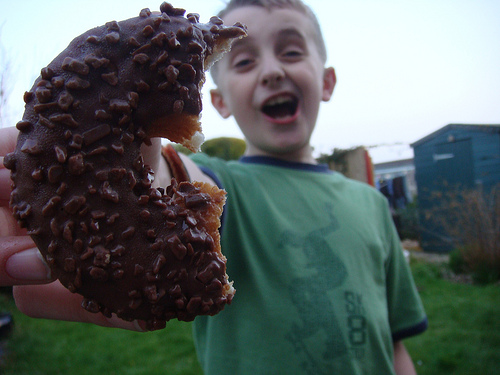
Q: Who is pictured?
A: Boy.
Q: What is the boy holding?
A: A donut.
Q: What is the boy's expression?
A: Happy.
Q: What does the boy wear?
A: A green shirt.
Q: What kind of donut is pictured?
A: Chocolate sprinkles and half eaten.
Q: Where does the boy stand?
A: On grass.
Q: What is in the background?
A: Buildings.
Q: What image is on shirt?
A: Silhouette of a skateboarder.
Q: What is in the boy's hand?
A: Chocolate doughnut.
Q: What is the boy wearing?
A: Green t-shirt.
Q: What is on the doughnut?
A: Chocolate sprinkles.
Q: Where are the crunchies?
A: On doughnut.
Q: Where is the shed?
A: Behind the boy.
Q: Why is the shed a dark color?
A: Owner painted green.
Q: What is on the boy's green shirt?
A: Black design.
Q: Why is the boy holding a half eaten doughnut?
A: Showing it to friends.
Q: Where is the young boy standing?
A: Center forefront.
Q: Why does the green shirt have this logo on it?
A: Boy skateboarder.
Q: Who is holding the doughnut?
A: Happy boy.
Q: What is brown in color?
A: The donut.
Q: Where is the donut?
A: In the kid's hand.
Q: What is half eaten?
A: The donut.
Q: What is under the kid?
A: Grass.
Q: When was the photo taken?
A: During the daytime.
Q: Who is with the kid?
A: No people.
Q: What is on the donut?
A: Sprinkles.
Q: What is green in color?
A: The shirt.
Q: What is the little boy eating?
A: A donut.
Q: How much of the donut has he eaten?
A: Half of the donut.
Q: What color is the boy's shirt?
A: Green.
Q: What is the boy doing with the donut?
A: Holding it out to show someone.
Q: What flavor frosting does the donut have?
A: Chocolate.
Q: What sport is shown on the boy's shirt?
A: Skateboarding.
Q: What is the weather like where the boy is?
A: Sunny and warm.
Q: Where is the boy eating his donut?
A: In the yard.